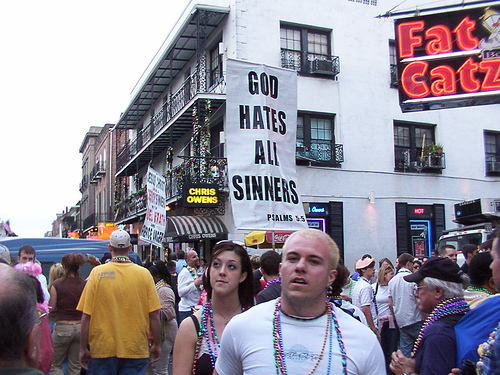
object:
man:
[208, 226, 390, 374]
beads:
[269, 291, 353, 374]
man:
[388, 251, 472, 371]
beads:
[409, 294, 469, 364]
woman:
[170, 237, 263, 374]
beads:
[190, 299, 251, 374]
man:
[71, 226, 166, 374]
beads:
[105, 253, 133, 266]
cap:
[108, 226, 133, 251]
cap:
[397, 253, 471, 285]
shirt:
[73, 259, 166, 364]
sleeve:
[76, 264, 100, 318]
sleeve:
[144, 274, 164, 319]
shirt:
[210, 296, 388, 374]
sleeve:
[212, 317, 245, 375]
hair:
[277, 227, 344, 273]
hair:
[418, 275, 465, 303]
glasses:
[209, 235, 247, 254]